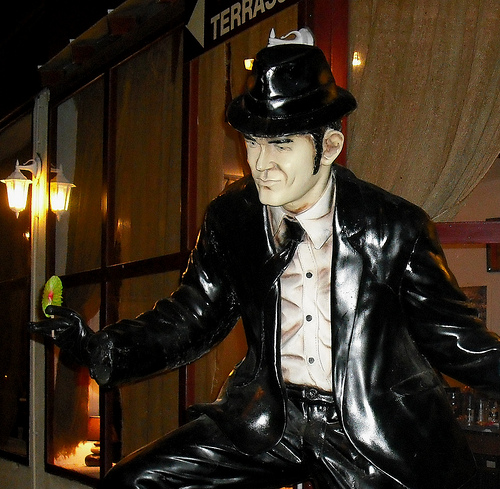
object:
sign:
[178, 0, 300, 69]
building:
[1, 0, 498, 485]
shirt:
[268, 209, 343, 389]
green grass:
[32, 257, 74, 328]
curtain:
[114, 40, 191, 460]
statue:
[35, 27, 498, 479]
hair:
[308, 131, 327, 174]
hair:
[255, 107, 364, 175]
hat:
[221, 40, 360, 135]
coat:
[88, 164, 497, 484]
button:
[304, 313, 311, 322]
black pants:
[91, 389, 399, 486]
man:
[46, 35, 487, 486]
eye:
[273, 142, 290, 154]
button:
[295, 268, 324, 286]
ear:
[321, 125, 345, 170]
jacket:
[104, 182, 497, 438]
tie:
[231, 214, 302, 314]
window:
[120, 110, 172, 222]